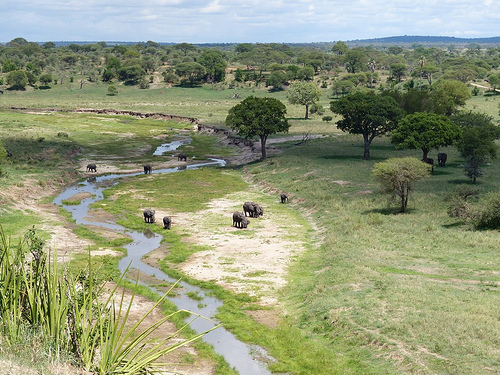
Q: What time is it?
A: Afternoon.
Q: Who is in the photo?
A: No people.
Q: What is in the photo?
A: Animals.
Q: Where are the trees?
A: On the ground.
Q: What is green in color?
A: The grass and trees.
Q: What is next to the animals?
A: Water.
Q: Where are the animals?
A: On the grass.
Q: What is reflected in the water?
A: An animal.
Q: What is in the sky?
A: Clouds.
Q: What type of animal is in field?
A: Elephants.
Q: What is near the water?
A: A large tree.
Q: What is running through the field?
A: A stream of water.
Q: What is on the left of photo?
A: Tall grass.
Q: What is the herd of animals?
A: Elephants.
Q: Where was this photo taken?
A: A stream.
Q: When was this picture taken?
A: Day time.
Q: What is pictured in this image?
A: Elephants.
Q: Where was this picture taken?
A: Africa.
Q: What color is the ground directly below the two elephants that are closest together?
A: White.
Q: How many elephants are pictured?
A: Nine.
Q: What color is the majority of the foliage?
A: Green.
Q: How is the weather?
A: Sunny, partly cloudy.